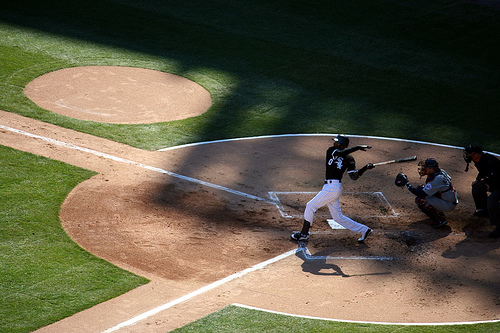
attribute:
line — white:
[117, 144, 256, 203]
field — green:
[233, 65, 378, 137]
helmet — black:
[317, 128, 369, 155]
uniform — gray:
[418, 176, 454, 205]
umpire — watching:
[454, 140, 497, 222]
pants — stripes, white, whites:
[288, 174, 378, 235]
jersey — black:
[303, 144, 373, 188]